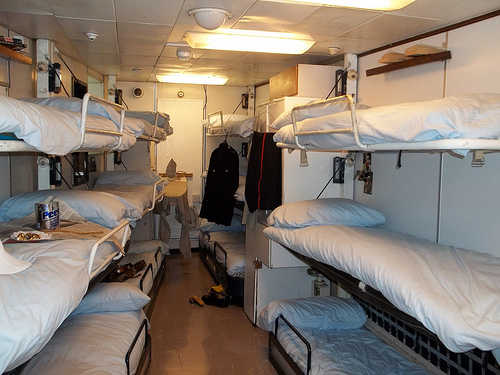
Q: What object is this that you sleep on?
A: Bed.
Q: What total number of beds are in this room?
A: 12.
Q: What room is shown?
A: Bedroom.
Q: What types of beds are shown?
A: Bunks.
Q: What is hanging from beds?
A: Uniforms.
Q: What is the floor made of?
A: Tile.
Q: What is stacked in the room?
A: Bunks.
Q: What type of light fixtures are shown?
A: Overhead lamps.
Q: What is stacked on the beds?
A: Pillows.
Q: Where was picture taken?
A: On ship.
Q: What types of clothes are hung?
A: Uniforms.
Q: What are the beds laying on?
A: Boards.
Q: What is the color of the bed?
A: White.